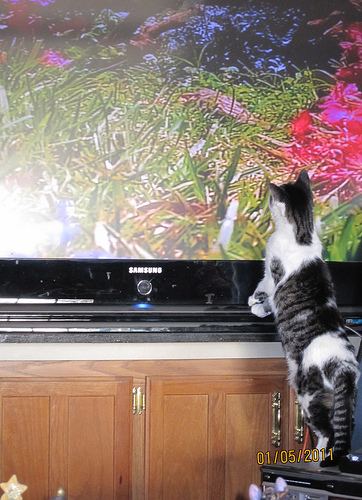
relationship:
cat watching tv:
[248, 168, 360, 468] [0, 0, 362, 333]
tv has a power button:
[0, 0, 362, 333] [137, 279, 153, 295]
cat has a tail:
[248, 168, 360, 468] [320, 371, 354, 467]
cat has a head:
[248, 168, 360, 468] [267, 168, 314, 223]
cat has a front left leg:
[248, 168, 360, 468] [247, 261, 281, 307]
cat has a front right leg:
[248, 168, 360, 468] [251, 296, 272, 318]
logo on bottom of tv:
[129, 267, 163, 273] [0, 0, 362, 333]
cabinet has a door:
[0, 326, 361, 500] [0, 375, 133, 499]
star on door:
[0, 473, 28, 499] [0, 375, 133, 499]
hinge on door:
[132, 387, 137, 414] [0, 375, 133, 499]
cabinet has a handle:
[0, 326, 361, 500] [272, 391, 282, 446]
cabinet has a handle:
[0, 326, 361, 500] [294, 397, 304, 444]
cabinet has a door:
[0, 326, 361, 500] [142, 374, 291, 500]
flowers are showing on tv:
[0, 0, 362, 262] [0, 0, 362, 333]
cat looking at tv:
[248, 168, 360, 468] [0, 0, 362, 333]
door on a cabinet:
[0, 375, 133, 499] [0, 326, 361, 500]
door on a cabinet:
[142, 374, 291, 500] [0, 326, 361, 500]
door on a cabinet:
[289, 386, 319, 461] [0, 326, 361, 500]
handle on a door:
[272, 391, 282, 446] [142, 374, 291, 500]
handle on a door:
[294, 397, 304, 444] [289, 386, 319, 461]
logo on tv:
[129, 267, 163, 273] [0, 0, 362, 333]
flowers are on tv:
[0, 0, 362, 262] [0, 0, 362, 333]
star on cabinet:
[0, 473, 28, 499] [0, 326, 361, 500]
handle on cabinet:
[272, 391, 282, 446] [0, 326, 361, 500]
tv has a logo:
[0, 0, 362, 333] [129, 267, 163, 273]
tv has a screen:
[0, 0, 362, 333] [0, 0, 362, 263]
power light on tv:
[136, 303, 150, 309] [0, 0, 362, 333]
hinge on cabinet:
[136, 387, 146, 414] [0, 326, 361, 500]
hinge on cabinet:
[132, 387, 137, 414] [0, 326, 361, 500]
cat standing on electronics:
[248, 168, 360, 468] [260, 456, 362, 499]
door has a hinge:
[0, 375, 133, 499] [132, 387, 137, 414]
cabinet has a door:
[0, 326, 361, 500] [289, 386, 319, 461]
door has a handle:
[142, 374, 291, 500] [272, 391, 282, 446]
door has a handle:
[289, 386, 319, 461] [294, 397, 304, 444]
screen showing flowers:
[0, 0, 362, 263] [0, 0, 362, 262]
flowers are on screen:
[0, 0, 362, 262] [0, 0, 362, 263]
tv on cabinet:
[0, 0, 362, 333] [0, 326, 361, 500]